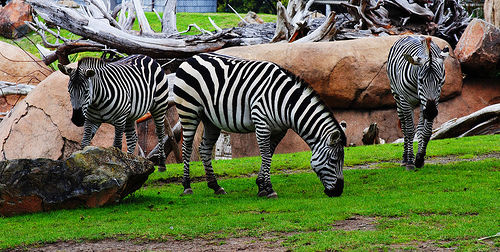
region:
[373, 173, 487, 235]
Bright green grass for the zebras.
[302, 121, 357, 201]
Zebra grazing on the grass.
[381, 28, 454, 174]
Zebra walking on the grass.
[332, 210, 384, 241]
Spot where the grass is not growing.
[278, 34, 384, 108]
Large rock in the background.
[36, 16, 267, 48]
Dead wood for decoration,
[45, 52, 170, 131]
Zebra looking down at the grass.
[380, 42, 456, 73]
Zebra ears on his head.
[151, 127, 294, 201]
Four legs on the zebra.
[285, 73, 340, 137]
Black mane on the zebra.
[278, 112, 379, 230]
the zebra is eating grass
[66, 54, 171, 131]
a black and white zebra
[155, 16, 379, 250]
a black and white zebra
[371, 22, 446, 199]
a black and white zebra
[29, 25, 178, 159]
a black and white zebra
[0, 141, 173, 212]
a big gray rock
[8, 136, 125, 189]
a big gray rock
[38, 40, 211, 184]
zebra's fur is stripes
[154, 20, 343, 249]
zebra's fur is stripes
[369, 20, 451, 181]
zebra's fur is stripes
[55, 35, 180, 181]
This is a zebra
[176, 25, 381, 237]
This is a zebra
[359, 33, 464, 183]
This is a zebra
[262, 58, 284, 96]
Black and white stripe on animal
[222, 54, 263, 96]
Black and white stripe on animal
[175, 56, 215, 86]
Black and white stripe on animal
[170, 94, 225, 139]
Black and white stripe on animal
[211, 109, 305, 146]
Black and white stripe on animal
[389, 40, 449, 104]
Black and white stripe on animal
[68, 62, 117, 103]
Black and white stripe on animal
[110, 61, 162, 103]
Black and white stripe on animal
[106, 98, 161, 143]
Black and white stripe on animal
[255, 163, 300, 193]
Black and white stripe on animal